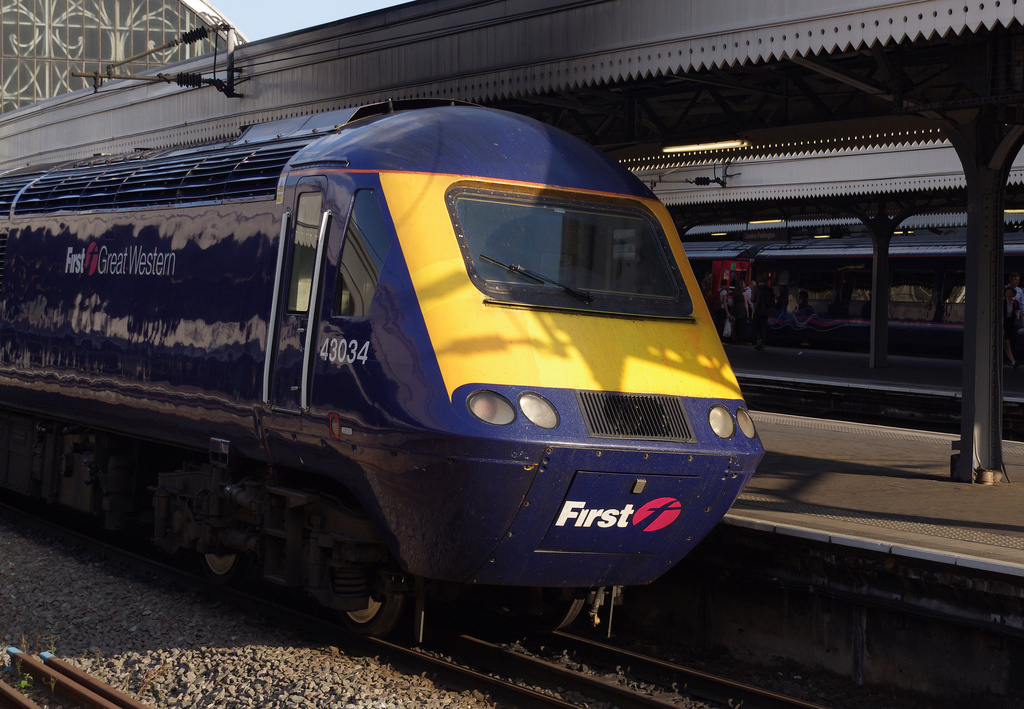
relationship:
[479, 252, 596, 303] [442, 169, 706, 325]
windshield wiper on windshield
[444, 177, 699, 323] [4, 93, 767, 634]
front window on train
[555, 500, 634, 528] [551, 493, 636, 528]
first spelling first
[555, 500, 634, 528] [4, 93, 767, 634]
first painted on train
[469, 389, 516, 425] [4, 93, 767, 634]
headlight built into train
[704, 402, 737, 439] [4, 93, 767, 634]
right headlight built into train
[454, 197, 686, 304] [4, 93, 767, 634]
front window built into train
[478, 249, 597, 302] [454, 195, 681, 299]
windshield wiper mounted on window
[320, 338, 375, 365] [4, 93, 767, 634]
number painted on train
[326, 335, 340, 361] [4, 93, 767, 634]
number painted on train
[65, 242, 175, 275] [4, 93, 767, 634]
great painted on train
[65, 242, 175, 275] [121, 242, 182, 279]
great spelling western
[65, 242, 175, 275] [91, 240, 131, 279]
great spelling great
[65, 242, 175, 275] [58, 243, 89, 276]
great spelling first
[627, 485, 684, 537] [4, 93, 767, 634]
emblem painted on train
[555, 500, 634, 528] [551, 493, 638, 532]
first spelling first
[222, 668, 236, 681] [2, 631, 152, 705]
rock lying next to track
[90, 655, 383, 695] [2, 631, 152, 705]
rock lying next to track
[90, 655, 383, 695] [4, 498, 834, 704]
rock lying next to track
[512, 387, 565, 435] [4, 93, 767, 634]
headlight built into train